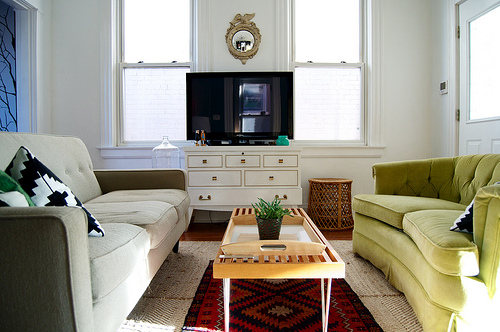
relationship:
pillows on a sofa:
[2, 144, 112, 244] [1, 115, 197, 329]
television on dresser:
[183, 71, 293, 145] [183, 147, 298, 224]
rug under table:
[184, 255, 384, 328] [212, 207, 344, 327]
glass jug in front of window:
[145, 128, 190, 175] [111, 0, 191, 137]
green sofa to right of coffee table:
[351, 150, 498, 330] [212, 202, 349, 329]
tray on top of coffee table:
[220, 212, 327, 256] [212, 202, 349, 329]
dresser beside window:
[187, 147, 304, 209] [294, 0, 365, 145]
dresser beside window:
[187, 147, 304, 209] [122, 0, 187, 142]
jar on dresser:
[272, 133, 291, 144] [184, 142, 304, 211]